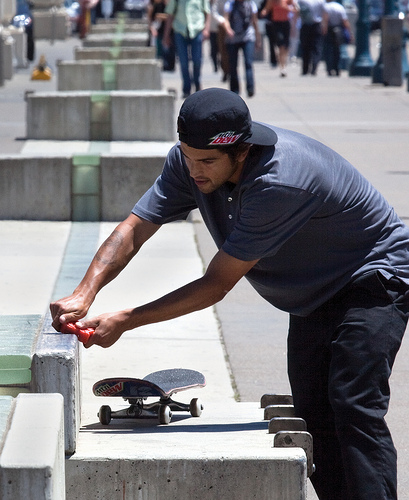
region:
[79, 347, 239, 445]
the skate board is black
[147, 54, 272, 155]
man's hat is black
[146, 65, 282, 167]
man's hat is on backwards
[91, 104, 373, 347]
man's shirt is gray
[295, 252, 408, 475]
man's pants are black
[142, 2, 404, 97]
people are walking in background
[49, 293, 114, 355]
man holding orange object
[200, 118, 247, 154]
green and red letters on hat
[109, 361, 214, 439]
skateboard wheels are white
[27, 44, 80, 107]
yellow object in background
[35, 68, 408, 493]
man bending over a skateboard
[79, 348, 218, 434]
the skateboard is black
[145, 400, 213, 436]
the wheels are white and black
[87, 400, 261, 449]
shadow on the concrete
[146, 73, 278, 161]
man is wearing a baseball hat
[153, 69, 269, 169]
the hat is turned backwards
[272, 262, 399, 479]
the pants are black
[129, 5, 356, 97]
people are walking down the street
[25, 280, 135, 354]
man holding a red object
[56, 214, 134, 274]
tattoo on the man`s forearm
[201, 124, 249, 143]
company name on side of hat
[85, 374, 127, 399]
company name on front of skateboard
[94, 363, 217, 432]
black skateboard sitting on concrete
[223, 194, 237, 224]
silver buttons on shirt of skateboarder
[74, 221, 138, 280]
tattoo on arm of skateboarder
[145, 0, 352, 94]
group of people walking on sidewalk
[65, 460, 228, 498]
black stains on side of concrete wall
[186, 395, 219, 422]
white hard plastic skateboard wheel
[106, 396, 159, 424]
silver metal skateboard wheel axel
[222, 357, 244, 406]
grass growing in crack of sidewalk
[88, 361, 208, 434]
a skateboard is on the cement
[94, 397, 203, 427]
silver trucks are on the skateboard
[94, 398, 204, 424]
the board has black and silver wheels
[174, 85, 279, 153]
the board has the cap on backwards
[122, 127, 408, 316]
the boy had a blue shirt on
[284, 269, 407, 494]
the pants are dark blue on the boy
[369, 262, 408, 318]
a pocket is in the pants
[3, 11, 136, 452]
lights are in the cement benches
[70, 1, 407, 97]
people are walking on the sidewalk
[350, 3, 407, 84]
poles are at the roadside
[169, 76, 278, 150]
The man is wearing a cap.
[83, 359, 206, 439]
The skateboard is on the step.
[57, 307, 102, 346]
The man has a red object in his hands.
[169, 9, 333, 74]
People walking down the sidewalk.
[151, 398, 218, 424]
The wheels on the skateboard.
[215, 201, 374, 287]
The man is wearing a blue shirt.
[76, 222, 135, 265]
The man has a tattoo.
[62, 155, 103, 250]
Lights around the cement steps.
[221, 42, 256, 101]
The person is wearing blue jeans.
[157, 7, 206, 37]
The man is wearing a green shirt.